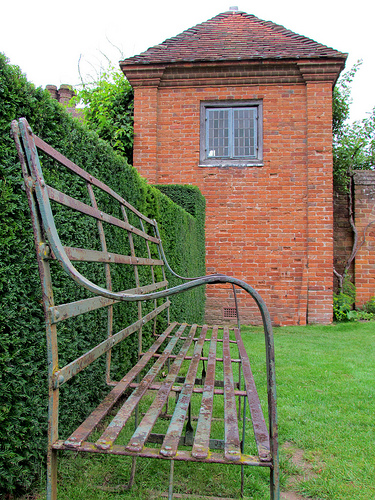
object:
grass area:
[277, 323, 362, 407]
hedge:
[0, 48, 208, 500]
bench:
[10, 116, 280, 500]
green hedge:
[4, 351, 46, 472]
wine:
[333, 176, 359, 290]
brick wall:
[333, 165, 375, 315]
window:
[199, 99, 264, 168]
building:
[118, 5, 374, 327]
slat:
[262, 328, 278, 455]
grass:
[302, 342, 360, 429]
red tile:
[197, 26, 264, 53]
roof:
[118, 4, 349, 66]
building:
[118, 4, 348, 326]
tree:
[333, 104, 375, 323]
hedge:
[0, 53, 205, 500]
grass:
[1, 316, 373, 500]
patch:
[280, 436, 315, 496]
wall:
[354, 184, 374, 313]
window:
[232, 107, 258, 160]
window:
[205, 106, 231, 159]